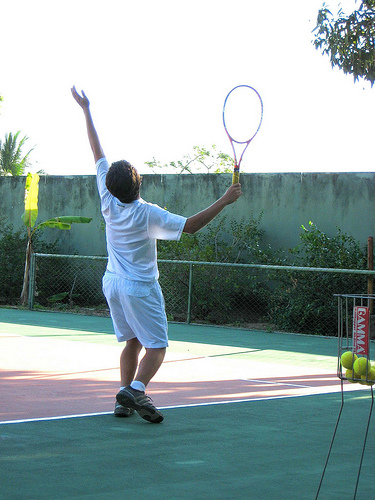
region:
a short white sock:
[129, 381, 145, 391]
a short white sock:
[118, 385, 125, 391]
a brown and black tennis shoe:
[116, 384, 164, 425]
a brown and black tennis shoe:
[113, 395, 134, 417]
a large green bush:
[265, 223, 367, 332]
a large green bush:
[155, 211, 274, 319]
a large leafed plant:
[17, 170, 93, 307]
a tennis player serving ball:
[68, 82, 263, 422]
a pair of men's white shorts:
[99, 270, 168, 349]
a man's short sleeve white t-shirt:
[94, 157, 186, 281]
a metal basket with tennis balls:
[309, 292, 372, 497]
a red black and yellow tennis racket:
[222, 83, 265, 185]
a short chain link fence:
[26, 253, 373, 334]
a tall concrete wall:
[2, 173, 373, 329]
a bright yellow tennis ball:
[342, 350, 357, 369]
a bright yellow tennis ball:
[353, 357, 371, 375]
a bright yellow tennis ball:
[345, 369, 359, 384]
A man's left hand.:
[70, 84, 89, 109]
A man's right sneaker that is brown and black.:
[117, 386, 163, 424]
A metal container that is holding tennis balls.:
[315, 293, 373, 499]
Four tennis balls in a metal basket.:
[340, 350, 374, 384]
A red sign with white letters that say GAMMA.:
[353, 304, 369, 355]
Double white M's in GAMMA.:
[356, 322, 365, 346]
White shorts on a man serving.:
[101, 270, 168, 349]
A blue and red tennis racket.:
[221, 85, 262, 184]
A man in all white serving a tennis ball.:
[70, 86, 241, 423]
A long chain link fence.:
[30, 251, 374, 339]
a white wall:
[1, 169, 372, 335]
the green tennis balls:
[338, 350, 374, 382]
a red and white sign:
[351, 301, 370, 354]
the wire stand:
[313, 284, 372, 498]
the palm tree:
[19, 169, 94, 304]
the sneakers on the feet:
[112, 382, 166, 425]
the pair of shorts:
[99, 268, 170, 351]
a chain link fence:
[25, 248, 372, 341]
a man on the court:
[68, 83, 266, 423]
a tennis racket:
[219, 82, 264, 199]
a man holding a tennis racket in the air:
[68, 64, 265, 424]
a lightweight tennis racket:
[221, 82, 263, 196]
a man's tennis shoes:
[113, 384, 166, 425]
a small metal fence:
[31, 250, 373, 344]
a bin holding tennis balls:
[314, 289, 373, 497]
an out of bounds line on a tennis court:
[2, 381, 339, 426]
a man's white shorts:
[101, 267, 172, 350]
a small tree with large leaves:
[17, 166, 89, 317]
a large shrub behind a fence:
[261, 223, 371, 338]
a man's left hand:
[70, 83, 91, 108]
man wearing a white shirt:
[69, 60, 273, 425]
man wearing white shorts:
[65, 76, 200, 432]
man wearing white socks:
[68, 90, 215, 427]